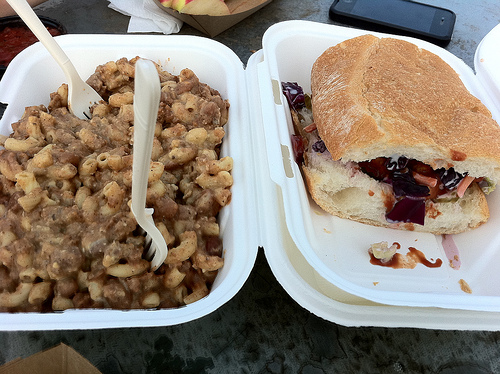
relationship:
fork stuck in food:
[119, 41, 181, 274] [24, 175, 126, 280]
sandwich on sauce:
[282, 31, 496, 235] [375, 152, 407, 186]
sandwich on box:
[301, 15, 498, 278] [231, 12, 497, 335]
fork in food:
[128, 54, 172, 272] [0, 55, 232, 314]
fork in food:
[20, 12, 82, 75] [18, 124, 124, 268]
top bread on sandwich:
[303, 30, 497, 188] [278, 22, 496, 248]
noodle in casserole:
[13, 121, 38, 153] [7, 57, 218, 292]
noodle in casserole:
[99, 151, 123, 166] [7, 57, 218, 292]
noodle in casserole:
[170, 139, 192, 157] [7, 57, 218, 292]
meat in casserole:
[42, 235, 74, 266] [7, 57, 218, 292]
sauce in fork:
[385, 240, 419, 275] [4, 1, 108, 117]